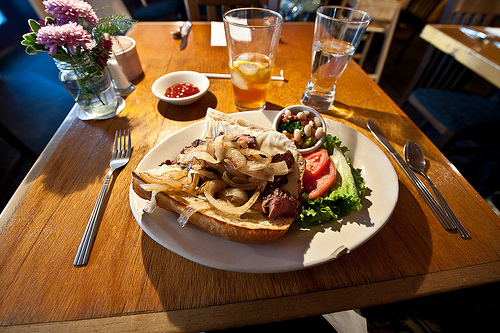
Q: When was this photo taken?
A: Yesterday.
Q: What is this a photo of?
A: A sandwich.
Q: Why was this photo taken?
A: For a souvenir.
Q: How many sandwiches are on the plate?
A: One.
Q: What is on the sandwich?
A: Onions.